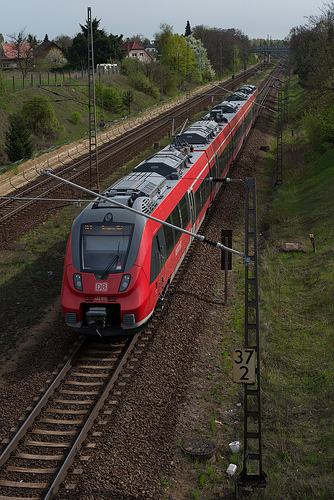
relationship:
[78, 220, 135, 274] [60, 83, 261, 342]
trains windshield on cars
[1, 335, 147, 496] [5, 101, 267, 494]
railroad track in rocks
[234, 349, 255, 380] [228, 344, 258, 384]
372 on sign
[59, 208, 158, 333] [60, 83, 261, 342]
end of cars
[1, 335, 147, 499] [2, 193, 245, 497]
railroad track in rocks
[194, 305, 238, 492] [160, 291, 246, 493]
grass in dirt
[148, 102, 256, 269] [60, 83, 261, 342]
windows on cars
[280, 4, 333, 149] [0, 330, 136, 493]
trees lining tracks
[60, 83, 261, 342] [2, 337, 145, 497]
cars on tracks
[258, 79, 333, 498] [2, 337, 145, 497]
grass between tracks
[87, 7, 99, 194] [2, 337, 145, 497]
structure between tracks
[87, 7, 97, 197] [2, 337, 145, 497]
structure over tracks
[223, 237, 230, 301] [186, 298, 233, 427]
pole sticking out of dirt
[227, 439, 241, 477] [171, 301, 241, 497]
trash on ground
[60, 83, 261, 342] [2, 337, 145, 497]
cars using tracks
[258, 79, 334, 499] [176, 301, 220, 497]
grass poking out of ground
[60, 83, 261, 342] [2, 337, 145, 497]
cars travelling down tracks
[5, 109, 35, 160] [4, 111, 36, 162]
foliage of a conifer tree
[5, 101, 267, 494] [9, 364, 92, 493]
rocks next to tracks